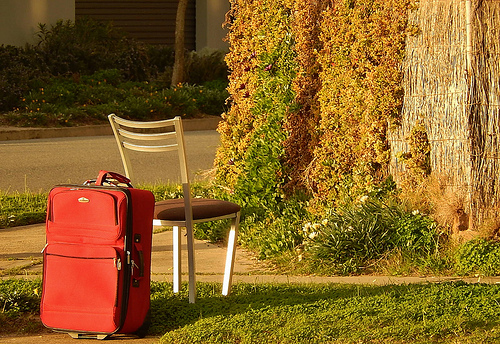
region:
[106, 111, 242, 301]
Chair behind red suitcase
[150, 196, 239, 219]
Brown cushion on chair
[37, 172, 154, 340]
Red suitcase standing by green grass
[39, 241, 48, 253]
Silver zipper on red suitcase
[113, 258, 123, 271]
Silver zipper on red suitcase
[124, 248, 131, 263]
Silver zipper on red suitcase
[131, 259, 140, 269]
Silver zipper on red suitcase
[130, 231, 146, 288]
Red handle on red suitcase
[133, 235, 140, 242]
Small silver button near red handle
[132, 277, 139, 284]
Small silver button near red handle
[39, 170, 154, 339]
red suitcase on ground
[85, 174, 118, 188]
handle on the suitcase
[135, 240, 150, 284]
handle on the sound of suitcase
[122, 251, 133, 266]
zipper on the suitcase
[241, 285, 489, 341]
green grass on the ground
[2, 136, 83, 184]
cement pavement in the street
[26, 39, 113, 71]
bushes in the grass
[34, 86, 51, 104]
flowers in the bushes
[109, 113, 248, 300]
white and brown chair outside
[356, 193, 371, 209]
flowers in the grass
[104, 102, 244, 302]
the chair is white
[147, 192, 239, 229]
chair cushion is brown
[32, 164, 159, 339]
suitcase behind the chair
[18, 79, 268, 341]
suitcase and chair in the grass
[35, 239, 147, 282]
silver zippers on suit case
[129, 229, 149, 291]
red and black handle on suitcase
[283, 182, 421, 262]
white flowers in the grass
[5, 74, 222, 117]
orange flowers in the grass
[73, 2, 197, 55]
the wall is brown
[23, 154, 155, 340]
the suitcase is closed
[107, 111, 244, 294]
a white and brown chair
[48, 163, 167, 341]
a red suitcase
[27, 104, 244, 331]
a suitcase behind a chair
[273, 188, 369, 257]
white flowers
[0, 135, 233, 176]
a street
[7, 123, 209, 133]
the curb on the street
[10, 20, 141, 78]
a bush behind the flowers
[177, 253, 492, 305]
the sidewalk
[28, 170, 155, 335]
red luggage on grass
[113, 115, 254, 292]
silver chair in grass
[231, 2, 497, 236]
tree with grass growing on it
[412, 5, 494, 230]
the trunk of a tree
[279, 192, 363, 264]
white flowers growing from grass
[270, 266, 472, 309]
sidewalk with grass on each side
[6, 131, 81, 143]
curb of the sidewalk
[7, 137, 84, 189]
a road that is empty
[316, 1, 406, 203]
brow grass growing on tree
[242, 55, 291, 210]
green and yellow grass growing on tree